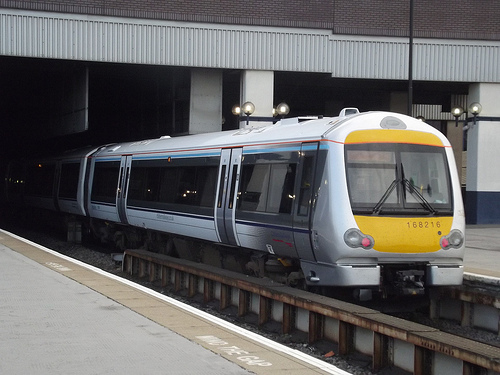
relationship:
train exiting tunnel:
[48, 105, 460, 302] [1, 47, 482, 217]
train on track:
[48, 105, 460, 302] [6, 247, 498, 366]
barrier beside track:
[182, 231, 410, 368] [29, 202, 499, 368]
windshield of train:
[342, 141, 454, 221] [18, 104, 473, 292]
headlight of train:
[346, 230, 373, 247] [18, 104, 473, 292]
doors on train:
[112, 141, 243, 251] [18, 104, 473, 292]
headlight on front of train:
[343, 228, 375, 251] [71, 92, 465, 279]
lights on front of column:
[232, 101, 289, 123] [235, 65, 278, 126]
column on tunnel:
[235, 65, 278, 126] [1, 52, 498, 144]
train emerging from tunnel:
[22, 107, 465, 301] [6, 56, 243, 248]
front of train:
[342, 125, 461, 256] [8, 103, 474, 317]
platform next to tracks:
[1, 233, 354, 373] [448, 332, 498, 348]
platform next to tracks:
[465, 224, 499, 283] [448, 332, 498, 348]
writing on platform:
[193, 321, 274, 371] [0, 228, 353, 375]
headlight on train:
[343, 228, 375, 251] [48, 105, 460, 302]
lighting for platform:
[443, 100, 484, 126] [465, 224, 499, 283]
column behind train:
[240, 68, 275, 129] [18, 104, 473, 292]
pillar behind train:
[466, 84, 499, 189] [18, 104, 473, 292]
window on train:
[124, 155, 220, 220] [48, 105, 460, 302]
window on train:
[231, 147, 299, 219] [48, 105, 460, 302]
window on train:
[87, 157, 122, 208] [48, 105, 460, 302]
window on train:
[52, 158, 83, 200] [48, 105, 460, 302]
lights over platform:
[227, 100, 481, 122] [465, 224, 499, 285]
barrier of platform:
[120, 231, 500, 368] [1, 233, 354, 373]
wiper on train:
[379, 180, 477, 215] [176, 93, 498, 273]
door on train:
[289, 137, 322, 259] [48, 105, 460, 302]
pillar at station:
[466, 82, 499, 225] [0, 0, 500, 375]